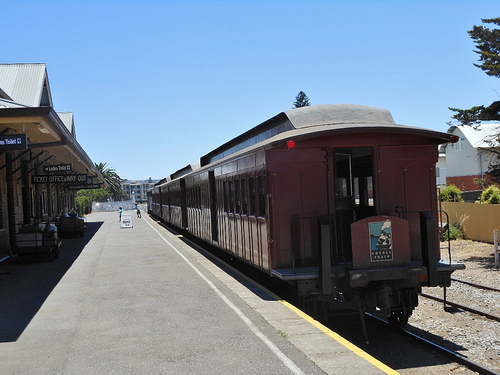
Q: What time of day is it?
A: Day time.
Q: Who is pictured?
A: No one.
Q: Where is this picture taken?
A: Train stop.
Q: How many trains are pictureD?
A: One.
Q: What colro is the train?
A: Burgandy.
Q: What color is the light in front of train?
A: Red.